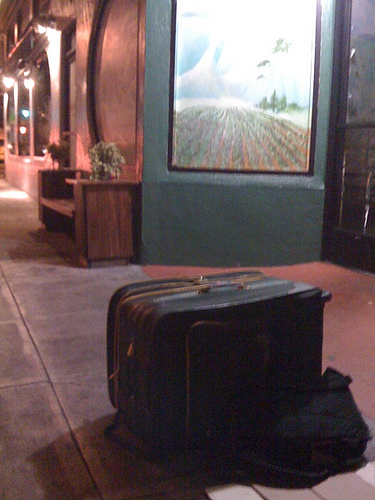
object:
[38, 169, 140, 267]
bench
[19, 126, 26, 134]
reflection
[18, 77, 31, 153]
window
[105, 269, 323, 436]
luggage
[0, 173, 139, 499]
sidewalk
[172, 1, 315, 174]
poster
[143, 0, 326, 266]
wall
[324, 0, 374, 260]
door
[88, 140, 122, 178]
plant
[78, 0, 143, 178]
wall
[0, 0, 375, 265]
building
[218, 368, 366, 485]
backpack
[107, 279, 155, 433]
trim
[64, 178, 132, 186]
arm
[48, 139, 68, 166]
plant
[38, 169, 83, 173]
arm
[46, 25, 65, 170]
column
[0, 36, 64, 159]
row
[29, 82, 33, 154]
column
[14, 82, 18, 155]
column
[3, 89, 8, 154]
column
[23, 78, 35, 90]
light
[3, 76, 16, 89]
light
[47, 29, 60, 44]
light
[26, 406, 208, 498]
shadow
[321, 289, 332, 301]
wheels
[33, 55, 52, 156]
window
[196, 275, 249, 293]
handle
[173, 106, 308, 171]
plants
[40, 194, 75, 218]
seat